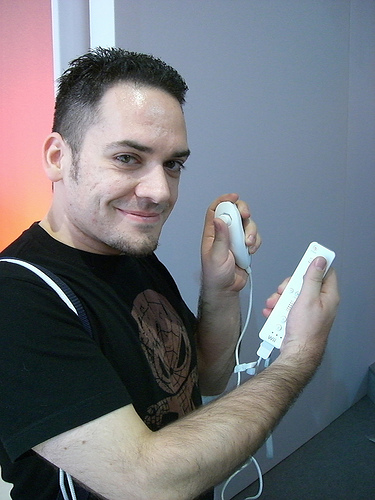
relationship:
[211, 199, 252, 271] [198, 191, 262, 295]
controllers in hands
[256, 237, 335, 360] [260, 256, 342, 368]
controller in hands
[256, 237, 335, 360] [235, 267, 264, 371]
controller has cord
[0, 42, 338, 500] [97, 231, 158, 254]
man has beard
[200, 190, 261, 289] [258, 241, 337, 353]
hand on controller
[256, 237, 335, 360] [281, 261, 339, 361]
controller in hand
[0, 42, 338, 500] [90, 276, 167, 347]
man wearing tee shirt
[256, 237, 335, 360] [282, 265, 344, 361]
controller held in hand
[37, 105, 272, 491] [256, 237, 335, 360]
man holding controller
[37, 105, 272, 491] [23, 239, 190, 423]
man wearing shirt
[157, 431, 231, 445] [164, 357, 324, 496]
hair growing on arm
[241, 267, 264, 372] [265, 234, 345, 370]
cord attached to remote